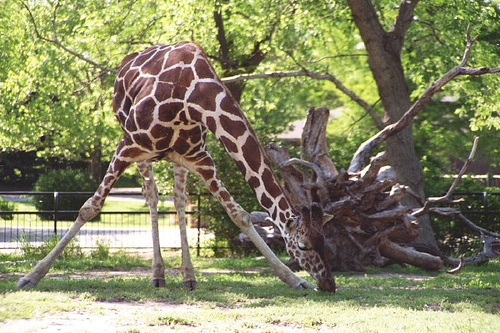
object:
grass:
[0, 269, 499, 332]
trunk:
[347, 1, 448, 270]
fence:
[1, 190, 228, 255]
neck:
[212, 120, 294, 210]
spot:
[138, 64, 179, 95]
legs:
[172, 160, 194, 268]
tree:
[286, 0, 499, 273]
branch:
[224, 48, 392, 129]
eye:
[298, 245, 311, 251]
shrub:
[32, 166, 101, 221]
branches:
[359, 160, 500, 237]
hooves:
[180, 280, 201, 290]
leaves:
[34, 54, 87, 129]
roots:
[285, 183, 446, 273]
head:
[277, 202, 335, 295]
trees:
[0, 0, 206, 183]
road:
[0, 217, 232, 252]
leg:
[163, 148, 288, 269]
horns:
[297, 203, 313, 229]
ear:
[285, 217, 299, 231]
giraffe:
[14, 40, 336, 295]